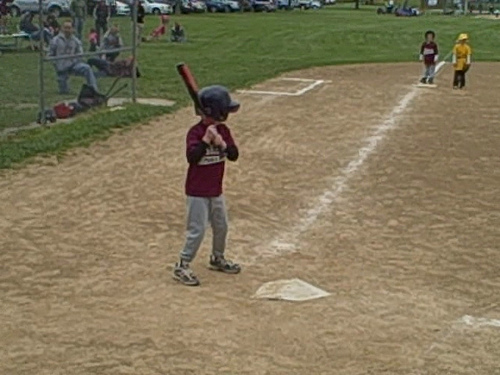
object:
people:
[84, 9, 161, 76]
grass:
[8, 126, 64, 149]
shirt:
[181, 112, 239, 199]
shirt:
[44, 32, 84, 70]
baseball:
[175, 59, 224, 157]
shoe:
[171, 263, 200, 287]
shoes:
[206, 257, 254, 277]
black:
[192, 82, 242, 122]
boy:
[400, 16, 445, 88]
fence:
[0, 2, 139, 132]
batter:
[170, 83, 242, 288]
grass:
[2, 13, 498, 69]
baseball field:
[1, 56, 498, 373]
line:
[251, 50, 452, 270]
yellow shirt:
[452, 43, 471, 70]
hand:
[214, 133, 225, 146]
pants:
[177, 192, 228, 259]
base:
[240, 264, 342, 316]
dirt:
[397, 193, 477, 267]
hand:
[202, 122, 215, 143]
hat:
[456, 31, 466, 38]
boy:
[449, 30, 474, 89]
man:
[35, 22, 100, 97]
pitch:
[343, 17, 482, 164]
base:
[410, 76, 442, 93]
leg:
[174, 190, 209, 265]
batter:
[160, 58, 251, 284]